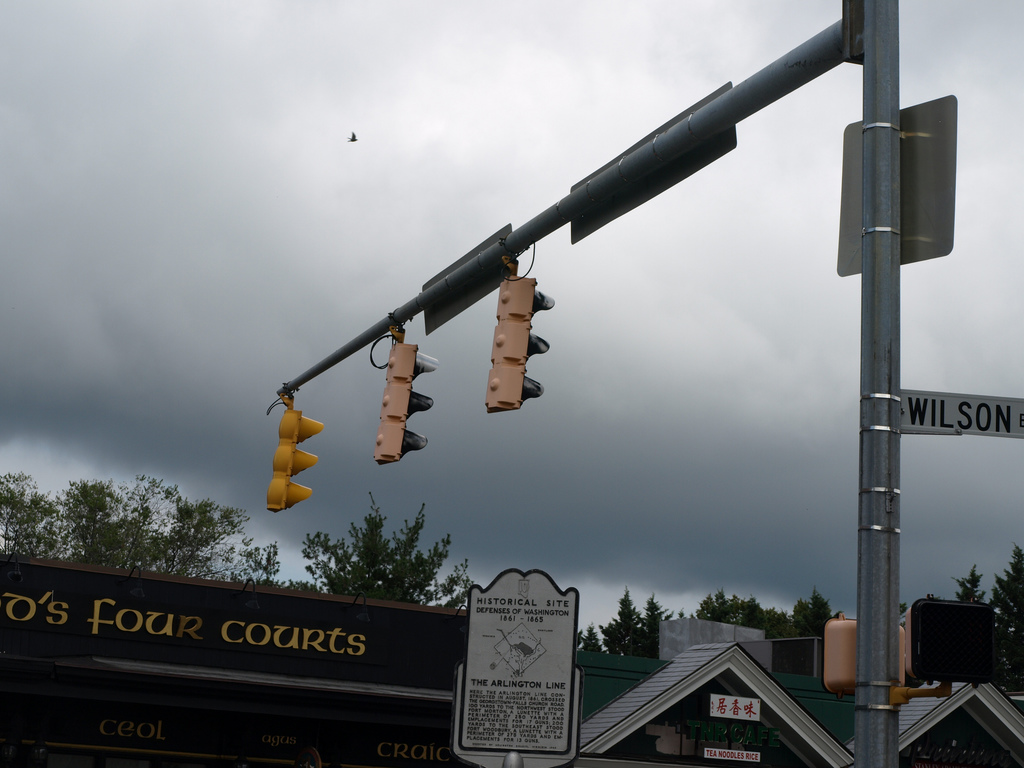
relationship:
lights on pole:
[266, 397, 330, 515] [841, 37, 932, 293]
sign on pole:
[912, 368, 1019, 466] [841, 37, 932, 293]